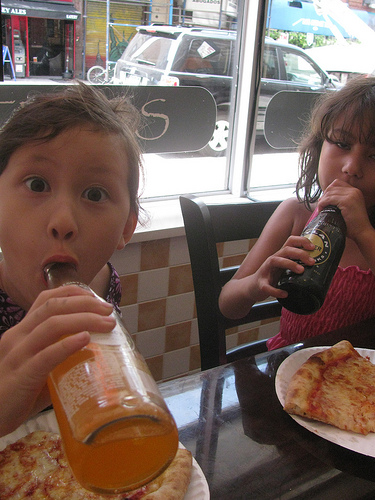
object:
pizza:
[0, 421, 194, 499]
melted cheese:
[321, 381, 360, 421]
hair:
[0, 81, 152, 234]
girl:
[218, 74, 375, 358]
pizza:
[284, 333, 374, 449]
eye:
[331, 137, 349, 152]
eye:
[364, 150, 374, 164]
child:
[0, 77, 152, 443]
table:
[1, 322, 375, 499]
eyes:
[13, 165, 56, 200]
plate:
[1, 400, 212, 498]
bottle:
[273, 190, 348, 317]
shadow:
[234, 366, 293, 451]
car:
[108, 22, 353, 166]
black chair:
[178, 193, 301, 375]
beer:
[275, 206, 353, 317]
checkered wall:
[106, 235, 284, 385]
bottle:
[39, 258, 180, 498]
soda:
[49, 330, 185, 494]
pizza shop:
[1, 0, 375, 498]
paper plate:
[272, 345, 375, 463]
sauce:
[112, 482, 149, 497]